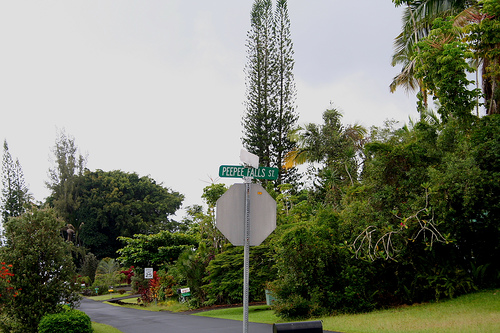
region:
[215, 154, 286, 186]
A green street sign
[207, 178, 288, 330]
A back view of a stop sign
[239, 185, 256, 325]
Stop sign is on the metal pole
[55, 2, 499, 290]
Trees are in the background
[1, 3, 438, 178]
The sky is cloudy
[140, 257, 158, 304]
A white sign is in the background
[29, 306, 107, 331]
A green bush in the foreground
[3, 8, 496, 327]
Photo was taken in the daytime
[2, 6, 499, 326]
Photo was taken outdoors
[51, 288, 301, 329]
The road is dark gray in color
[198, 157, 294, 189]
The sign reads Peepee Falls Street.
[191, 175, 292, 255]
A stop sign is beneath the street sign.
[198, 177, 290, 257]
The back of the stop sign is visible.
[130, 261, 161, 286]
A speed limit sign is in the background.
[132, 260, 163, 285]
The speed limit is 25 mph.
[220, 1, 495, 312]
Trees grow next to the street.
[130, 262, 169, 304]
A red plant is behind the sign.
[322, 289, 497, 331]
Grass is next to the street.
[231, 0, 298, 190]
The tree is tall and thin.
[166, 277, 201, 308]
A mailbox is next to the street.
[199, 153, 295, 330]
a red stop sign.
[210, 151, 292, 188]
a green stop sign.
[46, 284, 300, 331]
a paved road near a park.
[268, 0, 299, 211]
a tall leaf filled tree.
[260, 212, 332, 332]
a tree on a road side.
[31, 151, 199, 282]
a tall leaf filled tree.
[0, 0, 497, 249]
a cloudy blue sky.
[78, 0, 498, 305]
a tree filled forest.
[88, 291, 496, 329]
a green grass covered ground.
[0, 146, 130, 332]
A tree covered ground.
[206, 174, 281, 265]
back of a metal stop sign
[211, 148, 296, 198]
green peepee falls st sign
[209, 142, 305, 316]
metal street signs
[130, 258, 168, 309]
speed limit sign on a road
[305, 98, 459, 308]
green trees on a street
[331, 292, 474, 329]
grass on a street roadside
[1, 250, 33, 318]
red flowers of a green bush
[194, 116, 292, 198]
intersection street signs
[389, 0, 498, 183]
green palm trees behind bushes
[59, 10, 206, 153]
overcast blue sky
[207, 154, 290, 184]
Green street sign above stop sign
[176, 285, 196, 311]
mailbox on the side of the road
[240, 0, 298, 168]
Tall tree in the background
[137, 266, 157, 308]
Speed limit sign on the side of the road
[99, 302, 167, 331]
Black top road in residential area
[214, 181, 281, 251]
Back of a stop sign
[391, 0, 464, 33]
Palm tree leaves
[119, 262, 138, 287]
Small red tree in the distance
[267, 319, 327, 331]
Black barrel on road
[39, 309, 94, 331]
Green bush on the side of the road